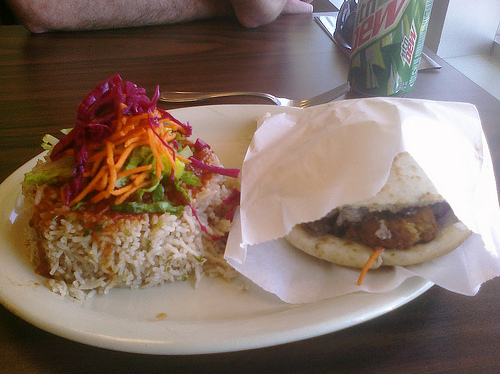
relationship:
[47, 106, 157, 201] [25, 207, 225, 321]
meal has rice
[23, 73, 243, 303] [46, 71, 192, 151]
meal has cabbage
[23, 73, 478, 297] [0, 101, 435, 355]
meal on plate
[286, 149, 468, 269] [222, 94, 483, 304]
meal inside bag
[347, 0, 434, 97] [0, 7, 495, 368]
soda on table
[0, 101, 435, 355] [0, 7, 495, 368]
plate on table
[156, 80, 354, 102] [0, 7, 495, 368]
fork on table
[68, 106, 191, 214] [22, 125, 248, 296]
carrots on top rice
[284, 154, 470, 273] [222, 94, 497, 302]
hamburger inside paper work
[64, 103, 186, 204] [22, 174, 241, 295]
vegetable on rice patty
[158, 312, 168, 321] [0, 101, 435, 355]
crumbs on plate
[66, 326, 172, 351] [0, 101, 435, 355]
edge of plate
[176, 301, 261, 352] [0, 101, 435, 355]
portion of plate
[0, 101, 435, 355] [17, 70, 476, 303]
plate with food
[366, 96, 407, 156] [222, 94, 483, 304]
crinkle appearing in bag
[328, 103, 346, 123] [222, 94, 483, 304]
crinkle appearing in bag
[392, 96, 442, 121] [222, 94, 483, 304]
crinkle appearing in bag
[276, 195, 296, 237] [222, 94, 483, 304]
crinkle appearing in bag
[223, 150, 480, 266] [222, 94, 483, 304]
edge lining bag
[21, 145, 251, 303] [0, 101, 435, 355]
rice lying on top of plate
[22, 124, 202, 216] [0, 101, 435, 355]
lettuce lying on top of plate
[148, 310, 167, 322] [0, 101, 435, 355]
crumb spilled on plate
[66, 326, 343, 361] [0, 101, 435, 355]
edge lining plate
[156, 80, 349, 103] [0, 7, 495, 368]
fork lying on top of table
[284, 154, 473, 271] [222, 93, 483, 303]
bun wrapped in paper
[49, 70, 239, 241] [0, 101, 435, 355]
vegetable lying on top of plate